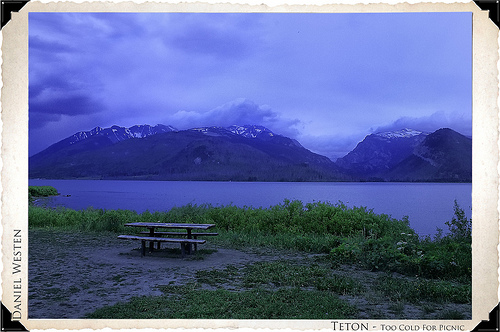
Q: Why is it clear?
A: To be seen.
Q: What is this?
A: Mountains.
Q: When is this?
A: Daytime.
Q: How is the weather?
A: Cloudy.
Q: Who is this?
A: No one.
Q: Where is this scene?
A: In a park.